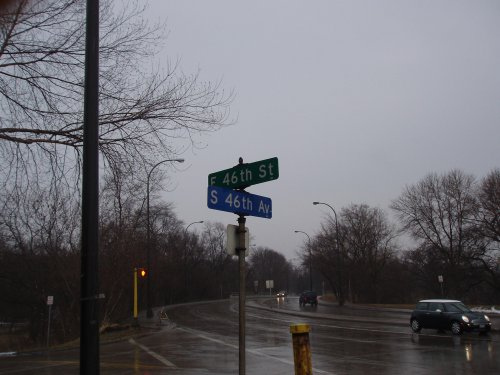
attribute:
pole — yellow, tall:
[129, 264, 140, 324]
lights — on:
[277, 290, 284, 295]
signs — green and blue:
[199, 145, 291, 222]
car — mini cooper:
[408, 300, 493, 337]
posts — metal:
[292, 194, 374, 294]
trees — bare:
[381, 149, 494, 286]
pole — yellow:
[288, 322, 315, 374]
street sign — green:
[206, 155, 280, 187]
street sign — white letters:
[206, 185, 271, 219]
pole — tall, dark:
[76, 2, 108, 374]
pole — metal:
[216, 234, 276, 374]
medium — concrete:
[245, 293, 412, 328]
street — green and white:
[4, 292, 496, 373]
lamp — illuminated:
[139, 265, 150, 278]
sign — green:
[208, 184, 277, 217]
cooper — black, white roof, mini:
[408, 294, 490, 336]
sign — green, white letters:
[196, 187, 291, 224]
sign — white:
[189, 156, 290, 206]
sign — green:
[208, 155, 278, 190]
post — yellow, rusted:
[286, 320, 311, 372]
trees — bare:
[388, 169, 493, 299]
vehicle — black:
[401, 279, 498, 341]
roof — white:
[411, 285, 463, 310]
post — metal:
[232, 211, 254, 374]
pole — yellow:
[171, 142, 294, 359]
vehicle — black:
[405, 290, 484, 340]